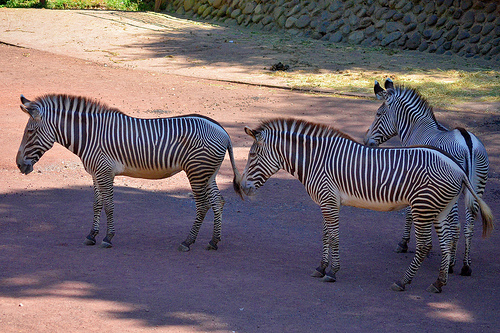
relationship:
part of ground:
[68, 13, 285, 84] [2, 8, 356, 99]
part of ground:
[78, 258, 292, 319] [5, 255, 310, 330]